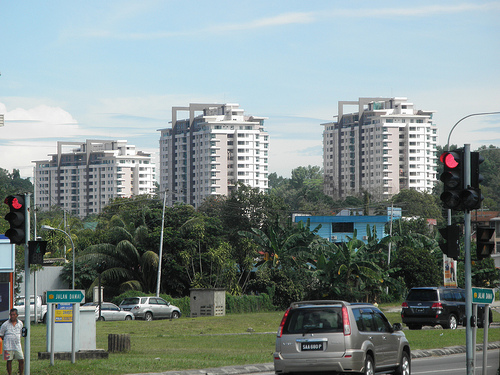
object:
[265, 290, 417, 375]
vehicle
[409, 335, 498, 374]
road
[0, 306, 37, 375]
person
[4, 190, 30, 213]
traffic light`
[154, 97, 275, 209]
building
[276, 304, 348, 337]
windows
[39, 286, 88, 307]
street sign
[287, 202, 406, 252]
structure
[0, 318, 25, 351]
shirt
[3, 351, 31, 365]
shorts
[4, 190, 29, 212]
light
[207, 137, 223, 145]
balconies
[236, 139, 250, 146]
windows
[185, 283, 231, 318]
transformer box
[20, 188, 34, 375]
pole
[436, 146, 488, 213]
casing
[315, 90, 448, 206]
buildings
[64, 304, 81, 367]
posts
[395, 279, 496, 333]
suv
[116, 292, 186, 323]
cars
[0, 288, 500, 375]
grass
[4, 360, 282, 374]
street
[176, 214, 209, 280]
trees